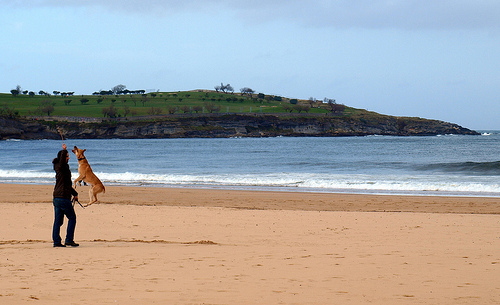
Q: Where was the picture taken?
A: It was taken at the beach.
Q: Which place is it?
A: It is a beach.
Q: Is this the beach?
A: Yes, it is the beach.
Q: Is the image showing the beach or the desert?
A: It is showing the beach.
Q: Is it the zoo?
A: No, it is the beach.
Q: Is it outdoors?
A: Yes, it is outdoors.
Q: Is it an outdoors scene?
A: Yes, it is outdoors.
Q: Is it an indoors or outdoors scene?
A: It is outdoors.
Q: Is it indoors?
A: No, it is outdoors.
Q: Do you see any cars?
A: No, there are no cars.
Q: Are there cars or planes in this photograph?
A: No, there are no cars or planes.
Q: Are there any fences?
A: No, there are no fences.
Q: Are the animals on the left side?
A: Yes, the animals are on the left of the image.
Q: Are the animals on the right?
A: No, the animals are on the left of the image.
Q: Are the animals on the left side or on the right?
A: The animals are on the left of the image.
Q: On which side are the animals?
A: The animals are on the left of the image.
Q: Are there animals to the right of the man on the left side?
A: Yes, there are animals to the right of the man.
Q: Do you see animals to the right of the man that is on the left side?
A: Yes, there are animals to the right of the man.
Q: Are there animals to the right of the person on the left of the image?
A: Yes, there are animals to the right of the man.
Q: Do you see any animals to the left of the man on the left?
A: No, the animals are to the right of the man.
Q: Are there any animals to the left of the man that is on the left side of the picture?
A: No, the animals are to the right of the man.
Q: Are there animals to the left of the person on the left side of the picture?
A: No, the animals are to the right of the man.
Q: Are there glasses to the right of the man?
A: No, there are animals to the right of the man.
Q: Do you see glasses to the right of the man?
A: No, there are animals to the right of the man.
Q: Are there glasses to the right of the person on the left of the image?
A: No, there are animals to the right of the man.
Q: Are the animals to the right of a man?
A: Yes, the animals are to the right of a man.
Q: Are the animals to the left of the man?
A: No, the animals are to the right of the man.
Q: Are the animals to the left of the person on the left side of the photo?
A: No, the animals are to the right of the man.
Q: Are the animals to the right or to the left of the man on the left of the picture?
A: The animals are to the right of the man.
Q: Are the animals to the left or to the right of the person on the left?
A: The animals are to the right of the man.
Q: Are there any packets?
A: No, there are no packets.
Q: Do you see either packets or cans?
A: No, there are no packets or cans.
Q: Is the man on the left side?
A: Yes, the man is on the left of the image.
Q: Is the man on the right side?
A: No, the man is on the left of the image.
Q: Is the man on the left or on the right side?
A: The man is on the left of the image.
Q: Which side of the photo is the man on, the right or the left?
A: The man is on the left of the image.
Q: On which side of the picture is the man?
A: The man is on the left of the image.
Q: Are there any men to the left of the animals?
A: Yes, there is a man to the left of the animals.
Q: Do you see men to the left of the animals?
A: Yes, there is a man to the left of the animals.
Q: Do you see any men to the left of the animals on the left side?
A: Yes, there is a man to the left of the animals.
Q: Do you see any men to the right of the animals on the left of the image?
A: No, the man is to the left of the animals.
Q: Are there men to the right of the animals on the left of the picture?
A: No, the man is to the left of the animals.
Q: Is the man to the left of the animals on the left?
A: Yes, the man is to the left of the animals.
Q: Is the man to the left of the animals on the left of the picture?
A: Yes, the man is to the left of the animals.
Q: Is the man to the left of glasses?
A: No, the man is to the left of the animals.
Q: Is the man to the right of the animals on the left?
A: No, the man is to the left of the animals.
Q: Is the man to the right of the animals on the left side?
A: No, the man is to the left of the animals.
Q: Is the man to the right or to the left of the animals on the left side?
A: The man is to the left of the animals.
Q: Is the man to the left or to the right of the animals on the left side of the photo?
A: The man is to the left of the animals.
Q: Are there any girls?
A: No, there are no girls.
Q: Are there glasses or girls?
A: No, there are no girls or glasses.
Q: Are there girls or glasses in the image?
A: No, there are no girls or glasses.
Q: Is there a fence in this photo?
A: No, there are no fences.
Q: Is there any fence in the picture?
A: No, there are no fences.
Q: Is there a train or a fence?
A: No, there are no fences or trains.